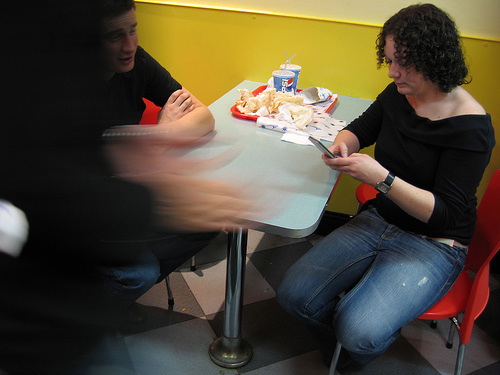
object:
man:
[41, 5, 216, 170]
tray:
[231, 79, 341, 124]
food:
[236, 86, 308, 121]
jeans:
[276, 210, 467, 355]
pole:
[216, 222, 256, 363]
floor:
[77, 206, 498, 375]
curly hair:
[371, 4, 473, 94]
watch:
[374, 172, 396, 194]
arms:
[93, 55, 217, 143]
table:
[95, 78, 379, 373]